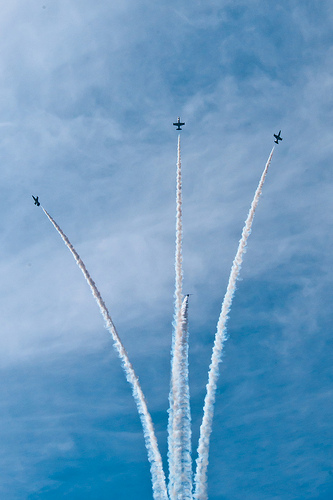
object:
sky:
[0, 0, 333, 499]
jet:
[273, 130, 283, 145]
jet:
[172, 116, 186, 130]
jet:
[183, 291, 193, 298]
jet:
[32, 193, 41, 207]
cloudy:
[1, 1, 333, 500]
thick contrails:
[168, 131, 182, 499]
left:
[31, 193, 168, 490]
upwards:
[168, 113, 188, 499]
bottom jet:
[181, 290, 191, 299]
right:
[194, 127, 286, 500]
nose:
[279, 129, 282, 134]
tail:
[274, 139, 279, 144]